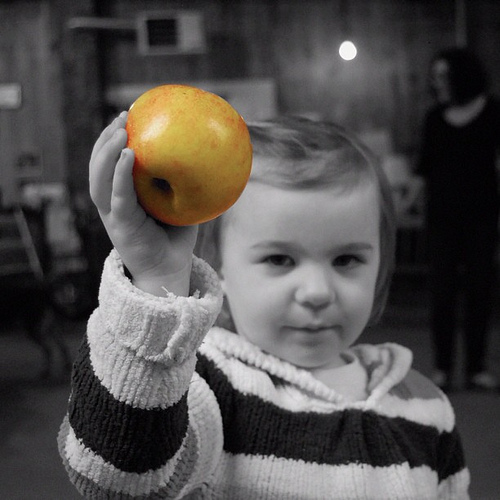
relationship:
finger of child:
[111, 150, 135, 215] [56, 109, 471, 499]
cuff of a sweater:
[91, 248, 223, 361] [61, 251, 471, 498]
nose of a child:
[298, 262, 336, 315] [56, 109, 471, 499]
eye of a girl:
[252, 253, 297, 267] [155, 85, 428, 405]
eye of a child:
[330, 252, 365, 269] [56, 109, 471, 499]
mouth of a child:
[282, 318, 342, 338] [50, 71, 465, 494]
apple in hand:
[124, 83, 253, 226] [84, 82, 254, 282]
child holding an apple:
[56, 109, 471, 499] [124, 83, 253, 226]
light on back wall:
[334, 36, 362, 65] [1, 0, 498, 131]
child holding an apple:
[50, 71, 465, 494] [124, 83, 253, 226]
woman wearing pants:
[401, 46, 500, 395] [428, 254, 488, 369]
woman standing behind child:
[385, 48, 499, 363] [50, 71, 465, 494]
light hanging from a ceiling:
[338, 40, 357, 61] [5, 7, 497, 64]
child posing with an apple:
[50, 71, 465, 494] [124, 83, 253, 226]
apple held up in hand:
[124, 83, 253, 226] [84, 82, 254, 282]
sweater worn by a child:
[61, 251, 471, 498] [44, 49, 486, 492]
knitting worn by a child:
[260, 400, 275, 417] [44, 49, 486, 492]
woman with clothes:
[401, 46, 500, 395] [412, 103, 496, 372]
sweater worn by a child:
[61, 251, 471, 498] [56, 109, 471, 499]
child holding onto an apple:
[50, 71, 465, 494] [126, 83, 251, 224]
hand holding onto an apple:
[89, 110, 199, 279] [126, 83, 251, 224]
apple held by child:
[129, 92, 231, 225] [244, 97, 386, 399]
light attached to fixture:
[338, 40, 357, 61] [336, 13, 352, 41]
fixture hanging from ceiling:
[336, 13, 352, 41] [0, 0, 499, 15]